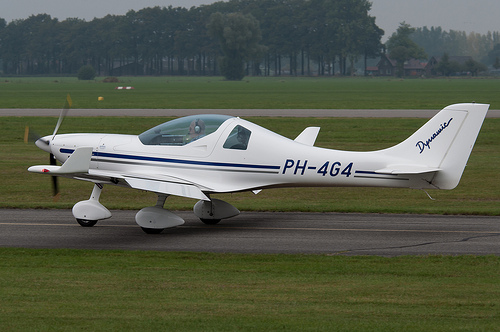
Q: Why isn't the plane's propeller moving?
A: Plane parked.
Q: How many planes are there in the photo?
A: 1.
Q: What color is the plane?
A: White.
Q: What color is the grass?
A: Green.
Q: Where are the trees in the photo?
A: On the right of the plane.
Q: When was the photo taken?
A: Day time.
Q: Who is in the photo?
A: No one.